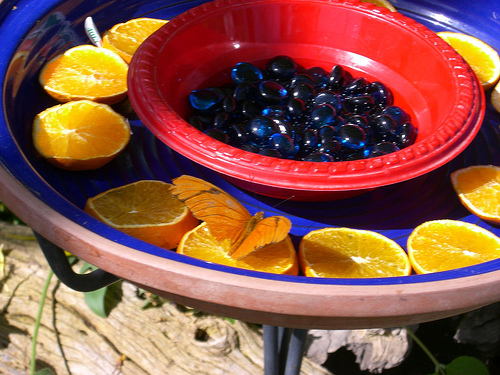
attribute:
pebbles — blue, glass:
[234, 67, 381, 143]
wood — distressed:
[3, 323, 235, 372]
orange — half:
[100, 15, 170, 65]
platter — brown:
[1, 3, 498, 323]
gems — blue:
[336, 123, 371, 148]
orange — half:
[138, 163, 452, 278]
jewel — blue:
[370, 81, 388, 106]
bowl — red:
[125, 0, 486, 201]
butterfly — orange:
[170, 174, 292, 259]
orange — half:
[84, 177, 198, 253]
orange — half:
[39, 39, 130, 101]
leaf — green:
[76, 262, 116, 318]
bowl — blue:
[0, 1, 498, 329]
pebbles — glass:
[164, 53, 384, 188]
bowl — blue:
[2, 4, 472, 364]